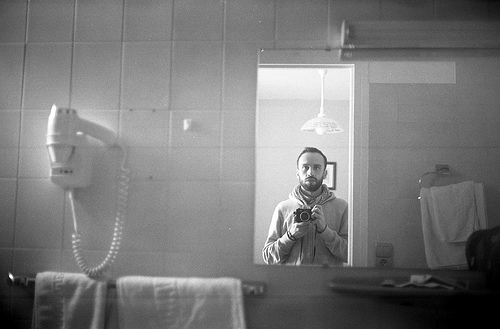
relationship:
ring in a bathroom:
[326, 273, 499, 298] [2, 10, 499, 321]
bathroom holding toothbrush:
[2, 10, 499, 321] [377, 276, 451, 293]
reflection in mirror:
[263, 150, 354, 265] [248, 47, 498, 273]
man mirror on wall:
[255, 65, 350, 266] [4, 3, 498, 327]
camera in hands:
[291, 208, 317, 223] [283, 203, 328, 233]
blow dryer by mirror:
[40, 94, 135, 282] [245, 39, 477, 263]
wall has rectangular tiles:
[4, 3, 498, 327] [102, 1, 232, 113]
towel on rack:
[115, 274, 245, 327] [5, 269, 265, 298]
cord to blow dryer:
[65, 161, 130, 281] [40, 94, 135, 282]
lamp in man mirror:
[294, 63, 344, 138] [255, 65, 350, 266]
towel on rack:
[30, 270, 109, 328] [6, 271, 266, 297]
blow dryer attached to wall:
[40, 94, 135, 282] [2, 7, 250, 275]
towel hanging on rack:
[30, 274, 265, 328] [5, 269, 265, 298]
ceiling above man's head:
[299, 67, 344, 141] [295, 145, 329, 188]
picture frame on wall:
[262, 146, 353, 264] [260, 99, 346, 269]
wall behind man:
[260, 99, 346, 269] [254, 140, 346, 259]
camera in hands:
[294, 208, 318, 221] [288, 204, 318, 224]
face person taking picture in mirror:
[261, 146, 349, 266] [248, 47, 498, 273]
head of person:
[289, 145, 326, 193] [261, 146, 350, 265]